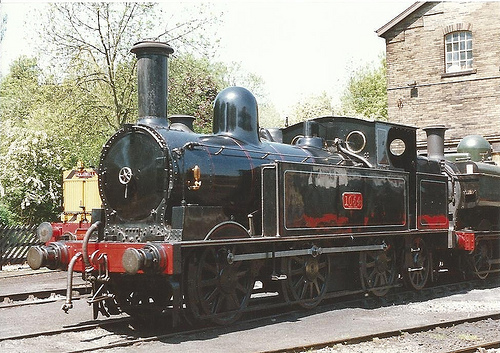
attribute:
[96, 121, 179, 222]
front is round — black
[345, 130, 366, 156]
window is circular — circle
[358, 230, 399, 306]
train has wheel — large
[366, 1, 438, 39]
building has roof — brick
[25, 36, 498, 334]
train — black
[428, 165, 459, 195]
bricks — brown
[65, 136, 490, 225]
train — black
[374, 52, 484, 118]
building — brown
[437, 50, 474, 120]
window — round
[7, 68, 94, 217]
trees — green and leafy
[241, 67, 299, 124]
sky — bright and white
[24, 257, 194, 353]
front — red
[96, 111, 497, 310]
train — black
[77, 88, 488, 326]
train — black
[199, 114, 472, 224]
train — black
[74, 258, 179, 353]
redpaint — red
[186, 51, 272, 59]
sky — blue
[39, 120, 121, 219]
building — yellow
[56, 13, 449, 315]
locomotive — old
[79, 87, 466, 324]
locomotive — historical